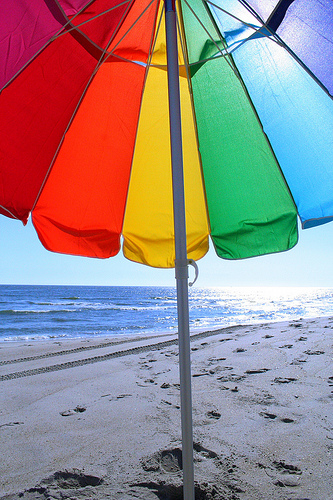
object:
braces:
[202, 0, 290, 55]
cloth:
[122, 0, 212, 271]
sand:
[280, 417, 295, 425]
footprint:
[273, 377, 297, 384]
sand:
[1, 316, 332, 499]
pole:
[164, 0, 195, 500]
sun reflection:
[235, 286, 295, 320]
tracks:
[0, 341, 176, 383]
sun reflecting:
[221, 1, 299, 69]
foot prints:
[53, 467, 105, 489]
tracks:
[190, 324, 249, 340]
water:
[0, 282, 330, 343]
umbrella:
[0, 0, 333, 273]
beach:
[0, 285, 331, 500]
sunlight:
[188, 279, 331, 321]